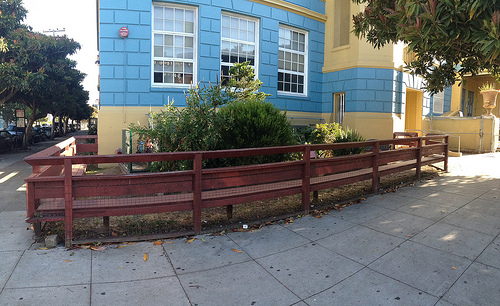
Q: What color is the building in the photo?
A: Blue and yellow.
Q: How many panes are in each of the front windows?
A: Twenty-four.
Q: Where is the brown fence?
A: Along the front and side of the building.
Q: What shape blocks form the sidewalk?
A: Square.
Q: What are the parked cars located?
A: Along the right side of the street on the left side of the building.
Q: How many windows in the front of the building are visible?
A: Three.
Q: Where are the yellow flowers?
A: To the right of the large green shrub.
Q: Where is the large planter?
A: On the wall to the left of the door.